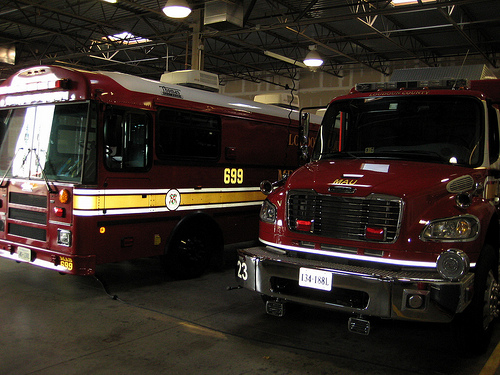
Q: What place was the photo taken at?
A: It was taken at the garage.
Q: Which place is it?
A: It is a garage.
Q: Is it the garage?
A: Yes, it is the garage.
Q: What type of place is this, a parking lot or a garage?
A: It is a garage.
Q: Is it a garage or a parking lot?
A: It is a garage.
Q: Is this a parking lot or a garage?
A: It is a garage.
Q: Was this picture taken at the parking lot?
A: No, the picture was taken in the garage.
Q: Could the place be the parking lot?
A: No, it is the garage.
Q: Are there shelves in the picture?
A: No, there are no shelves.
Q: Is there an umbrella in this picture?
A: No, there are no umbrellas.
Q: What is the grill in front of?
A: The grill is in front of the fire truck.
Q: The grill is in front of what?
A: The grill is in front of the fire truck.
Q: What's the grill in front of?
A: The grill is in front of the fire truck.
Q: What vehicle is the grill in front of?
A: The grill is in front of the fire truck.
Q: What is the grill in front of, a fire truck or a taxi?
A: The grill is in front of a fire truck.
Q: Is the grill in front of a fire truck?
A: Yes, the grill is in front of a fire truck.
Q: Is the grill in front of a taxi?
A: No, the grill is in front of a fire truck.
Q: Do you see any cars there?
A: No, there are no cars.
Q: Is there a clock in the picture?
A: No, there are no clocks.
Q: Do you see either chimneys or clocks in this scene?
A: No, there are no clocks or chimneys.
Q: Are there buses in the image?
A: Yes, there is a bus.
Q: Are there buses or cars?
A: Yes, there is a bus.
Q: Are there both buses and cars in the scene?
A: No, there is a bus but no cars.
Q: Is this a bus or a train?
A: This is a bus.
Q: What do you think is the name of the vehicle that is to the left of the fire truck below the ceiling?
A: The vehicle is a bus.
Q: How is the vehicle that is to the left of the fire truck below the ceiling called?
A: The vehicle is a bus.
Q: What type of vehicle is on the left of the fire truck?
A: The vehicle is a bus.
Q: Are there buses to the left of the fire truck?
A: Yes, there is a bus to the left of the fire truck.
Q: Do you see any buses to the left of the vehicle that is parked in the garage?
A: Yes, there is a bus to the left of the fire truck.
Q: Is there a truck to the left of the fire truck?
A: No, there is a bus to the left of the fire truck.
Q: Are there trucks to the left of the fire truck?
A: No, there is a bus to the left of the fire truck.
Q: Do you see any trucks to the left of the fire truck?
A: No, there is a bus to the left of the fire truck.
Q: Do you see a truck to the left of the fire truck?
A: No, there is a bus to the left of the fire truck.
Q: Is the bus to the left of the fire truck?
A: Yes, the bus is to the left of the fire truck.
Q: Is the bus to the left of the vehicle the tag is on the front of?
A: Yes, the bus is to the left of the fire truck.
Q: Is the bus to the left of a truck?
A: No, the bus is to the left of the fire truck.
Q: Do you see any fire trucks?
A: Yes, there is a fire truck.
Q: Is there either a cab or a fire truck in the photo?
A: Yes, there is a fire truck.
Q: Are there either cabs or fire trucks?
A: Yes, there is a fire truck.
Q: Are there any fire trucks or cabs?
A: Yes, there is a fire truck.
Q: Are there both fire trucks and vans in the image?
A: No, there is a fire truck but no vans.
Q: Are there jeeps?
A: No, there are no jeeps.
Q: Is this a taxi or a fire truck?
A: This is a fire truck.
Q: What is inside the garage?
A: The fire truck is inside the garage.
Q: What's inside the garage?
A: The fire truck is inside the garage.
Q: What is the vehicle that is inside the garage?
A: The vehicle is a fire truck.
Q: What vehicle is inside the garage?
A: The vehicle is a fire truck.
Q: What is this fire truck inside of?
A: The fire truck is inside the garage.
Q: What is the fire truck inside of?
A: The fire truck is inside the garage.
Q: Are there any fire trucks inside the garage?
A: Yes, there is a fire truck inside the garage.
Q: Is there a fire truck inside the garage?
A: Yes, there is a fire truck inside the garage.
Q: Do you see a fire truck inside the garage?
A: Yes, there is a fire truck inside the garage.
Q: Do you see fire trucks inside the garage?
A: Yes, there is a fire truck inside the garage.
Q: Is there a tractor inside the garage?
A: No, there is a fire truck inside the garage.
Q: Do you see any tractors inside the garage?
A: No, there is a fire truck inside the garage.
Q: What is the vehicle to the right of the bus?
A: The vehicle is a fire truck.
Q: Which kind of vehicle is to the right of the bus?
A: The vehicle is a fire truck.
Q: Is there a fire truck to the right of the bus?
A: Yes, there is a fire truck to the right of the bus.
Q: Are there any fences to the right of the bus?
A: No, there is a fire truck to the right of the bus.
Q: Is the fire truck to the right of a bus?
A: Yes, the fire truck is to the right of a bus.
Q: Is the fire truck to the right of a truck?
A: No, the fire truck is to the right of a bus.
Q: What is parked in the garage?
A: The fire truck is parked in the garage.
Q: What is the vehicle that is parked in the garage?
A: The vehicle is a fire truck.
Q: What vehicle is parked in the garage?
A: The vehicle is a fire truck.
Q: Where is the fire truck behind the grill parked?
A: The fire truck is parked in the garage.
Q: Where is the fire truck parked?
A: The fire truck is parked in the garage.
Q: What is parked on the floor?
A: The fire truck is parked on the floor.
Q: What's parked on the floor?
A: The fire truck is parked on the floor.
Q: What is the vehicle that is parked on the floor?
A: The vehicle is a fire truck.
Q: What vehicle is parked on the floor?
A: The vehicle is a fire truck.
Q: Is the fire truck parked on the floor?
A: Yes, the fire truck is parked on the floor.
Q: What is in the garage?
A: The fire truck is in the garage.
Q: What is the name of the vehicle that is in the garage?
A: The vehicle is a fire truck.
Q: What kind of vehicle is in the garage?
A: The vehicle is a fire truck.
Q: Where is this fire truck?
A: The fire truck is in the garage.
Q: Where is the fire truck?
A: The fire truck is in the garage.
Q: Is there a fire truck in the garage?
A: Yes, there is a fire truck in the garage.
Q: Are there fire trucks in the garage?
A: Yes, there is a fire truck in the garage.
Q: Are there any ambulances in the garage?
A: No, there is a fire truck in the garage.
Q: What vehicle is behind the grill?
A: The vehicle is a fire truck.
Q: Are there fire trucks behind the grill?
A: Yes, there is a fire truck behind the grill.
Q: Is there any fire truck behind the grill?
A: Yes, there is a fire truck behind the grill.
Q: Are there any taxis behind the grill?
A: No, there is a fire truck behind the grill.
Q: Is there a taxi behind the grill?
A: No, there is a fire truck behind the grill.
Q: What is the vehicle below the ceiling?
A: The vehicle is a fire truck.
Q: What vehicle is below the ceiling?
A: The vehicle is a fire truck.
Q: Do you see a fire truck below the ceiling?
A: Yes, there is a fire truck below the ceiling.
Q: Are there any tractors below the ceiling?
A: No, there is a fire truck below the ceiling.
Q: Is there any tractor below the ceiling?
A: No, there is a fire truck below the ceiling.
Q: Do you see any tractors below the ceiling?
A: No, there is a fire truck below the ceiling.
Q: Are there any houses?
A: No, there are no houses.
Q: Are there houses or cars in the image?
A: No, there are no houses or cars.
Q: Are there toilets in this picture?
A: No, there are no toilets.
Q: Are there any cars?
A: No, there are no cars.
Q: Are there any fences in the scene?
A: No, there are no fences.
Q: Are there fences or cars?
A: No, there are no fences or cars.